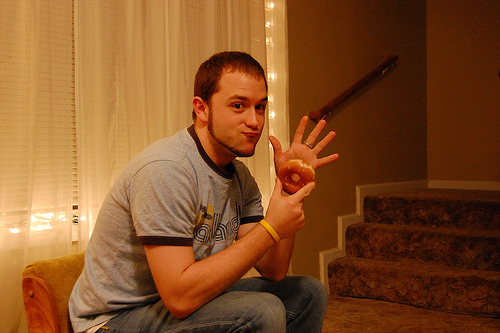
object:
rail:
[308, 54, 399, 124]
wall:
[286, 0, 500, 191]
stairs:
[327, 194, 500, 318]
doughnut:
[278, 158, 316, 196]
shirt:
[68, 123, 264, 333]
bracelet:
[259, 219, 281, 243]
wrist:
[257, 217, 284, 249]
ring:
[302, 140, 312, 148]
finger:
[303, 120, 326, 149]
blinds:
[71, 1, 77, 209]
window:
[0, 0, 287, 254]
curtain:
[0, 0, 71, 256]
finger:
[311, 131, 336, 155]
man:
[68, 50, 339, 333]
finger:
[317, 153, 339, 168]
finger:
[293, 115, 310, 142]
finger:
[268, 135, 284, 162]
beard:
[207, 102, 214, 137]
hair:
[191, 52, 228, 121]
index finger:
[291, 179, 317, 203]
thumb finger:
[272, 177, 283, 196]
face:
[208, 74, 269, 157]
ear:
[192, 96, 208, 123]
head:
[191, 51, 269, 157]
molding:
[427, 177, 500, 190]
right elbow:
[163, 307, 202, 320]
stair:
[326, 256, 500, 319]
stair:
[363, 195, 500, 231]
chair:
[21, 251, 87, 333]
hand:
[268, 115, 339, 177]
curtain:
[73, 0, 192, 126]